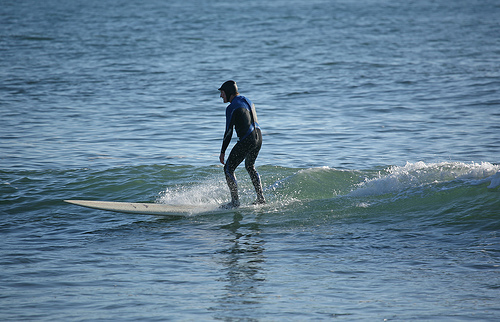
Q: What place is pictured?
A: It is an ocean.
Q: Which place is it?
A: It is an ocean.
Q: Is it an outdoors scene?
A: Yes, it is outdoors.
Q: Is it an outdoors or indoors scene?
A: It is outdoors.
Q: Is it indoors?
A: No, it is outdoors.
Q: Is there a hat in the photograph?
A: Yes, there is a hat.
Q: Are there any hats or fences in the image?
A: Yes, there is a hat.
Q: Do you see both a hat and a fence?
A: No, there is a hat but no fences.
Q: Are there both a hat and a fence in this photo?
A: No, there is a hat but no fences.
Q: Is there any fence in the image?
A: No, there are no fences.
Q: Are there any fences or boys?
A: No, there are no fences or boys.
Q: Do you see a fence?
A: No, there are no fences.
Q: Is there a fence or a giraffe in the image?
A: No, there are no fences or giraffes.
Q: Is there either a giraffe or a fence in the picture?
A: No, there are no fences or giraffes.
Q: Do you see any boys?
A: No, there are no boys.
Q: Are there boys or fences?
A: No, there are no boys or fences.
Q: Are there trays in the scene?
A: No, there are no trays.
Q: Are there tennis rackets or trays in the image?
A: No, there are no trays or tennis rackets.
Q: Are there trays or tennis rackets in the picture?
A: No, there are no trays or tennis rackets.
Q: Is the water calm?
A: Yes, the water is calm.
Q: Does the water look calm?
A: Yes, the water is calm.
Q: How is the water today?
A: The water is calm.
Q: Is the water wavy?
A: No, the water is calm.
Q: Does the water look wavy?
A: No, the water is calm.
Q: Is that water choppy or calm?
A: The water is calm.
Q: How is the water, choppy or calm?
A: The water is calm.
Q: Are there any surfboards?
A: Yes, there is a surfboard.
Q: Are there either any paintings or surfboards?
A: Yes, there is a surfboard.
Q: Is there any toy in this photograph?
A: No, there are no toys.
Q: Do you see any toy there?
A: No, there are no toys.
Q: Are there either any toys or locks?
A: No, there are no toys or locks.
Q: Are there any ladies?
A: No, there are no ladies.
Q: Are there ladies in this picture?
A: No, there are no ladies.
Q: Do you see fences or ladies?
A: No, there are no ladies or fences.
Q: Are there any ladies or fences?
A: No, there are no ladies or fences.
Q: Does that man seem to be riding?
A: Yes, the man is riding.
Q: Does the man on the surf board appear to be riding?
A: Yes, the man is riding.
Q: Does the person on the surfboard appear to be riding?
A: Yes, the man is riding.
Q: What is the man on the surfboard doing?
A: The man is riding.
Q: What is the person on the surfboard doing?
A: The man is riding.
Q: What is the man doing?
A: The man is riding.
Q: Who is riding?
A: The man is riding.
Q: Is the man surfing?
A: No, the man is riding.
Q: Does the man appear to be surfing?
A: No, the man is riding.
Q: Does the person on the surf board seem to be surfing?
A: No, the man is riding.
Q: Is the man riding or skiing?
A: The man is riding.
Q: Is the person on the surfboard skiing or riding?
A: The man is riding.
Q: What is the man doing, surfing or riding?
A: The man is riding.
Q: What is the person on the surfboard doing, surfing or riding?
A: The man is riding.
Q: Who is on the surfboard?
A: The man is on the surfboard.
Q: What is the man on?
A: The man is on the surfboard.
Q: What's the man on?
A: The man is on the surfboard.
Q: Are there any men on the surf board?
A: Yes, there is a man on the surf board.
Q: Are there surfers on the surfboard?
A: No, there is a man on the surfboard.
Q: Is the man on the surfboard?
A: Yes, the man is on the surfboard.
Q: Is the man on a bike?
A: No, the man is on the surfboard.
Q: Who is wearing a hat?
A: The man is wearing a hat.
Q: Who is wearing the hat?
A: The man is wearing a hat.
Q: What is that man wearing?
A: The man is wearing a hat.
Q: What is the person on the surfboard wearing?
A: The man is wearing a hat.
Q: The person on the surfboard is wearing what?
A: The man is wearing a hat.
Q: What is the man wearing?
A: The man is wearing a hat.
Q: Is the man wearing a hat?
A: Yes, the man is wearing a hat.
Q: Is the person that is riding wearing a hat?
A: Yes, the man is wearing a hat.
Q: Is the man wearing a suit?
A: No, the man is wearing a hat.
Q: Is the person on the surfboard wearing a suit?
A: No, the man is wearing a hat.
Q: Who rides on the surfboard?
A: The man rides on the surfboard.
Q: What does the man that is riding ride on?
A: The man rides on the surfboard.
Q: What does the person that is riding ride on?
A: The man rides on the surfboard.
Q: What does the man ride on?
A: The man rides on the surfboard.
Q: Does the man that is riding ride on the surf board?
A: Yes, the man rides on the surf board.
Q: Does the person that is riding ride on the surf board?
A: Yes, the man rides on the surf board.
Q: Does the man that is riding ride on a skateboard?
A: No, the man rides on the surf board.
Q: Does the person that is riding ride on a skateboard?
A: No, the man rides on the surf board.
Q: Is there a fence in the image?
A: No, there are no fences.